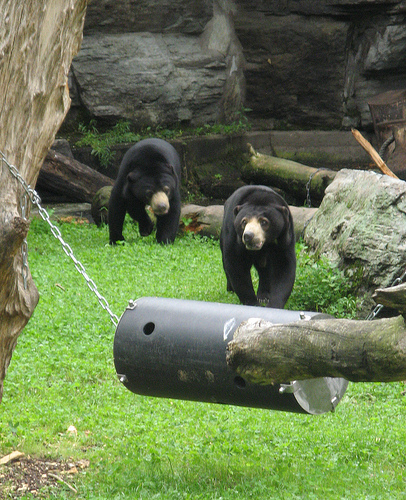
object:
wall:
[68, 0, 227, 135]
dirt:
[0, 447, 92, 499]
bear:
[107, 136, 185, 247]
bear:
[219, 182, 297, 309]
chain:
[0, 151, 119, 328]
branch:
[350, 126, 399, 180]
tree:
[0, 0, 88, 401]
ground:
[323, 49, 345, 87]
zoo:
[0, 0, 406, 500]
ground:
[0, 217, 406, 500]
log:
[239, 142, 338, 208]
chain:
[306, 167, 328, 207]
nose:
[243, 231, 255, 242]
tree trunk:
[1, 0, 86, 391]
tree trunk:
[240, 143, 338, 207]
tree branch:
[225, 314, 406, 386]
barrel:
[113, 295, 349, 415]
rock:
[303, 166, 406, 321]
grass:
[0, 219, 406, 500]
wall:
[236, 0, 353, 132]